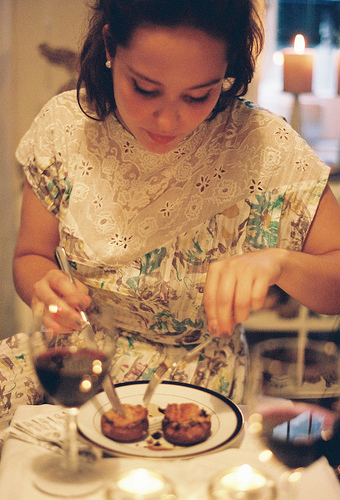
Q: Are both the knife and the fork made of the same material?
A: Yes, both the knife and the fork are made of metal.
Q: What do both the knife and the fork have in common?
A: The material, both the knife and the fork are metallic.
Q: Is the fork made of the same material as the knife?
A: Yes, both the fork and the knife are made of metal.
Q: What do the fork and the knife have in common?
A: The material, both the fork and the knife are metallic.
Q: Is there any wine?
A: Yes, there is wine.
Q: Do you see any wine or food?
A: Yes, there is wine.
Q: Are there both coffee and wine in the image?
A: No, there is wine but no coffee.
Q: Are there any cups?
A: No, there are no cups.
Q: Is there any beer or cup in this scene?
A: No, there are no cups or beer.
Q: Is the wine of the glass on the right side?
A: No, the wine is on the left of the image.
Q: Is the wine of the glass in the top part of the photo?
A: No, the wine is in the bottom of the image.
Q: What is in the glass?
A: The wine is in the glass.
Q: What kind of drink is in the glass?
A: The drink is wine.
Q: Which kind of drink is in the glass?
A: The drink is wine.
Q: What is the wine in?
A: The wine is in the glass.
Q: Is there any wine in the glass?
A: Yes, there is wine in the glass.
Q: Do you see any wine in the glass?
A: Yes, there is wine in the glass.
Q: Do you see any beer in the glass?
A: No, there is wine in the glass.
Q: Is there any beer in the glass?
A: No, there is wine in the glass.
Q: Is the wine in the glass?
A: Yes, the wine is in the glass.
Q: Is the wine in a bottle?
A: No, the wine is in the glass.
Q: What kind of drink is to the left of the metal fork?
A: The drink is wine.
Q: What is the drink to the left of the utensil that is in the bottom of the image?
A: The drink is wine.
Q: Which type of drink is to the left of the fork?
A: The drink is wine.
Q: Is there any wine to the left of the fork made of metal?
A: Yes, there is wine to the left of the fork.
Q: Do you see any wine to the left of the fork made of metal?
A: Yes, there is wine to the left of the fork.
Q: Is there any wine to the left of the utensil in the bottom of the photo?
A: Yes, there is wine to the left of the fork.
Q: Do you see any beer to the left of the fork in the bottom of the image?
A: No, there is wine to the left of the fork.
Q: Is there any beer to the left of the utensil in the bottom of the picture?
A: No, there is wine to the left of the fork.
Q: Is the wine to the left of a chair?
A: No, the wine is to the left of the fork.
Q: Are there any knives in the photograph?
A: Yes, there is a knife.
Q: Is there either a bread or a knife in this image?
A: Yes, there is a knife.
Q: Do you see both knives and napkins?
A: Yes, there are both a knife and a napkin.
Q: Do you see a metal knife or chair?
A: Yes, there is a metal knife.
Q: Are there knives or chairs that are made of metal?
A: Yes, the knife is made of metal.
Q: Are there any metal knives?
A: Yes, there is a knife that is made of metal.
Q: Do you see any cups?
A: No, there are no cups.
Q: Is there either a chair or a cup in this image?
A: No, there are no cups or chairs.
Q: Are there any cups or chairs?
A: No, there are no cups or chairs.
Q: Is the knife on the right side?
A: No, the knife is on the left of the image.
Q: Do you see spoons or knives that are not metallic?
A: No, there is a knife but it is metallic.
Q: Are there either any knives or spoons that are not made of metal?
A: No, there is a knife but it is made of metal.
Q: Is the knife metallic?
A: Yes, the knife is metallic.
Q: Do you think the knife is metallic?
A: Yes, the knife is metallic.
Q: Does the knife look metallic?
A: Yes, the knife is metallic.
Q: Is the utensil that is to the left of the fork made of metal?
A: Yes, the knife is made of metal.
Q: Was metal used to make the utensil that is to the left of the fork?
A: Yes, the knife is made of metal.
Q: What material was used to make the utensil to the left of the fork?
A: The knife is made of metal.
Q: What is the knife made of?
A: The knife is made of metal.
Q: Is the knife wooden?
A: No, the knife is metallic.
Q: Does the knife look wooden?
A: No, the knife is metallic.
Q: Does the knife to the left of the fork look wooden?
A: No, the knife is metallic.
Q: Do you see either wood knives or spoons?
A: No, there is a knife but it is metallic.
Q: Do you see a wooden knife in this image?
A: No, there is a knife but it is metallic.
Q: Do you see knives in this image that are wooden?
A: No, there is a knife but it is metallic.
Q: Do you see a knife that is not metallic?
A: No, there is a knife but it is metallic.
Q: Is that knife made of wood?
A: No, the knife is made of metal.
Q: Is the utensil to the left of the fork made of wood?
A: No, the knife is made of metal.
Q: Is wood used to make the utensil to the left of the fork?
A: No, the knife is made of metal.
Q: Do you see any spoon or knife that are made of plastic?
A: No, there is a knife but it is made of metal.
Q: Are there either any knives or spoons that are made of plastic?
A: No, there is a knife but it is made of metal.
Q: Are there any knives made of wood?
A: No, there is a knife but it is made of metal.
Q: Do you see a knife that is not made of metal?
A: No, there is a knife but it is made of metal.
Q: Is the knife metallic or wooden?
A: The knife is metallic.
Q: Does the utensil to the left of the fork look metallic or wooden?
A: The knife is metallic.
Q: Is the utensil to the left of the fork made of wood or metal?
A: The knife is made of metal.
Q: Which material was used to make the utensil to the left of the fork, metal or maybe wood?
A: The knife is made of metal.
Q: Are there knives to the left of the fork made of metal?
A: Yes, there is a knife to the left of the fork.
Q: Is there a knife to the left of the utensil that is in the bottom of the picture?
A: Yes, there is a knife to the left of the fork.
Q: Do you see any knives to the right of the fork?
A: No, the knife is to the left of the fork.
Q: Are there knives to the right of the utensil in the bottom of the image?
A: No, the knife is to the left of the fork.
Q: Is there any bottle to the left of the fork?
A: No, there is a knife to the left of the fork.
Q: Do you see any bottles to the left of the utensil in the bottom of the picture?
A: No, there is a knife to the left of the fork.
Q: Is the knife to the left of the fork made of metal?
A: Yes, the knife is to the left of the fork.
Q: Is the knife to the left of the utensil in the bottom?
A: Yes, the knife is to the left of the fork.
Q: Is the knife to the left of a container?
A: No, the knife is to the left of the fork.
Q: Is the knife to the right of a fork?
A: No, the knife is to the left of a fork.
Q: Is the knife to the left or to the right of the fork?
A: The knife is to the left of the fork.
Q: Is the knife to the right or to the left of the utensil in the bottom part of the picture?
A: The knife is to the left of the fork.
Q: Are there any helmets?
A: No, there are no helmets.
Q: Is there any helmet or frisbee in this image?
A: No, there are no helmets or frisbees.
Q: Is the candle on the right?
A: Yes, the candle is on the right of the image.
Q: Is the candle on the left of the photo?
A: No, the candle is on the right of the image.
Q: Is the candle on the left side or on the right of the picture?
A: The candle is on the right of the image.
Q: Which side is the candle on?
A: The candle is on the right of the image.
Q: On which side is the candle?
A: The candle is on the right of the image.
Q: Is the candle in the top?
A: Yes, the candle is in the top of the image.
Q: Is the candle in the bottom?
A: No, the candle is in the top of the image.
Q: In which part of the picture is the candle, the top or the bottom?
A: The candle is in the top of the image.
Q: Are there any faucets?
A: No, there are no faucets.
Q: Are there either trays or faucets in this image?
A: No, there are no faucets or trays.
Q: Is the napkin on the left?
A: Yes, the napkin is on the left of the image.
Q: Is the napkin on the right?
A: No, the napkin is on the left of the image.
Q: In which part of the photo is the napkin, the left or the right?
A: The napkin is on the left of the image.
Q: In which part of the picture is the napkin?
A: The napkin is on the left of the image.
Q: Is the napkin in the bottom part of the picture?
A: Yes, the napkin is in the bottom of the image.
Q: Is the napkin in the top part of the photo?
A: No, the napkin is in the bottom of the image.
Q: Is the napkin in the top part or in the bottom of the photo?
A: The napkin is in the bottom of the image.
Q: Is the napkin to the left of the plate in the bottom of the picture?
A: Yes, the napkin is to the left of the plate.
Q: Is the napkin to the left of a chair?
A: No, the napkin is to the left of the plate.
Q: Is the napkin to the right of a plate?
A: No, the napkin is to the left of a plate.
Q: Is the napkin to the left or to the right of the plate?
A: The napkin is to the left of the plate.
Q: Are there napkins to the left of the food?
A: Yes, there is a napkin to the left of the food.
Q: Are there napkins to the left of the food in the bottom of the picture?
A: Yes, there is a napkin to the left of the food.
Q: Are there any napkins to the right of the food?
A: No, the napkin is to the left of the food.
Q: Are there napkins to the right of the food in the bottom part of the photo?
A: No, the napkin is to the left of the food.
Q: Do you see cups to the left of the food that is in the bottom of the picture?
A: No, there is a napkin to the left of the food.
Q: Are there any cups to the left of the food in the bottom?
A: No, there is a napkin to the left of the food.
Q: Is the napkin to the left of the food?
A: Yes, the napkin is to the left of the food.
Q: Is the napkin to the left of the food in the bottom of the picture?
A: Yes, the napkin is to the left of the food.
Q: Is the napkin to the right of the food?
A: No, the napkin is to the left of the food.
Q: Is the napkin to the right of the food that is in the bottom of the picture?
A: No, the napkin is to the left of the food.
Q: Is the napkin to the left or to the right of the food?
A: The napkin is to the left of the food.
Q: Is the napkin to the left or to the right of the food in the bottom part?
A: The napkin is to the left of the food.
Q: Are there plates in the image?
A: Yes, there is a plate.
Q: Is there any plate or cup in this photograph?
A: Yes, there is a plate.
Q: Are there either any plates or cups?
A: Yes, there is a plate.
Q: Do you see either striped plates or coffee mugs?
A: Yes, there is a striped plate.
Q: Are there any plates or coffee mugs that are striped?
A: Yes, the plate is striped.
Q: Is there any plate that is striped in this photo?
A: Yes, there is a striped plate.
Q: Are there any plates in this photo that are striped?
A: Yes, there is a plate that is striped.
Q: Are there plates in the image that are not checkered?
A: Yes, there is a striped plate.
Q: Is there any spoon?
A: No, there are no spoons.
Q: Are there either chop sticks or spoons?
A: No, there are no spoons or chop sticks.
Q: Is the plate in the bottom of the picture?
A: Yes, the plate is in the bottom of the image.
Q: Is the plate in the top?
A: No, the plate is in the bottom of the image.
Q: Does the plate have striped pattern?
A: Yes, the plate is striped.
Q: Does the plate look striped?
A: Yes, the plate is striped.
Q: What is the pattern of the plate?
A: The plate is striped.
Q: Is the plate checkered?
A: No, the plate is striped.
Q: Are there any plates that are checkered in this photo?
A: No, there is a plate but it is striped.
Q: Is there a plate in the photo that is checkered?
A: No, there is a plate but it is striped.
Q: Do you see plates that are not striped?
A: No, there is a plate but it is striped.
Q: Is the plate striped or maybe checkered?
A: The plate is striped.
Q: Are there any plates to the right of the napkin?
A: Yes, there is a plate to the right of the napkin.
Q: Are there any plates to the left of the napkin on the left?
A: No, the plate is to the right of the napkin.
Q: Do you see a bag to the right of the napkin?
A: No, there is a plate to the right of the napkin.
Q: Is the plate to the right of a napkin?
A: Yes, the plate is to the right of a napkin.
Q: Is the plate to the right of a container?
A: No, the plate is to the right of a napkin.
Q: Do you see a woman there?
A: Yes, there is a woman.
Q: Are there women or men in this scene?
A: Yes, there is a woman.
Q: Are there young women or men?
A: Yes, there is a young woman.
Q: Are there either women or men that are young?
A: Yes, the woman is young.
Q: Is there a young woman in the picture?
A: Yes, there is a young woman.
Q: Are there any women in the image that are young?
A: Yes, there is a woman that is young.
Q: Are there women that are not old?
A: Yes, there is an young woman.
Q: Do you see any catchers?
A: No, there are no catchers.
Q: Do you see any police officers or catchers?
A: No, there are no catchers or police officers.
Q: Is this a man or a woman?
A: This is a woman.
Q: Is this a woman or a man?
A: This is a woman.